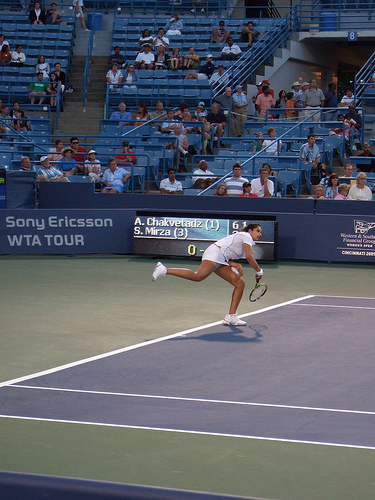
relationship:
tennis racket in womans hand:
[249, 271, 268, 301] [255, 272, 262, 280]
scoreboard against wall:
[133, 210, 274, 243] [3, 202, 357, 265]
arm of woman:
[238, 231, 266, 278] [142, 200, 294, 329]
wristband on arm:
[253, 265, 267, 276] [238, 231, 266, 278]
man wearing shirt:
[225, 161, 247, 195] [224, 176, 249, 195]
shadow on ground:
[163, 320, 264, 343] [2, 254, 374, 499]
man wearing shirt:
[157, 165, 184, 193] [160, 177, 184, 189]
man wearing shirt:
[299, 129, 326, 191] [300, 145, 321, 156]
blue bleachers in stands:
[138, 71, 213, 98] [1, 0, 373, 201]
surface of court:
[3, 293, 373, 455] [2, 292, 372, 448]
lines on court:
[83, 382, 212, 444] [2, 292, 372, 448]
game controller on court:
[150, 223, 268, 326] [2, 292, 372, 448]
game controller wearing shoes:
[150, 223, 268, 326] [152, 261, 165, 280]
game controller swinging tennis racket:
[150, 223, 268, 326] [248, 276, 265, 302]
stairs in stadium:
[51, 26, 114, 152] [0, 0, 374, 499]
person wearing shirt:
[58, 147, 78, 174] [56, 159, 75, 170]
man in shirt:
[225, 161, 247, 195] [224, 175, 248, 194]